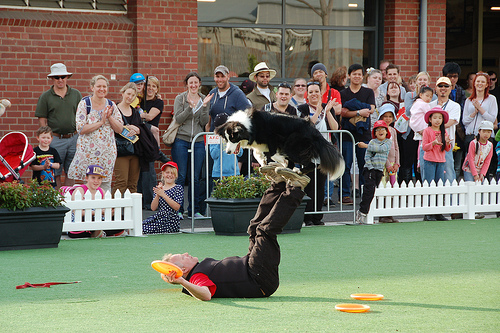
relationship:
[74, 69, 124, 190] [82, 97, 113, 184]
woman wearing dress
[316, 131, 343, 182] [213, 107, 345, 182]
tail of dog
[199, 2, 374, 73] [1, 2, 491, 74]
window on building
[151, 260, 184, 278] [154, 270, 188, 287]
frisbee in hand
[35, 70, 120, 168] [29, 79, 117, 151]
man wearing shirt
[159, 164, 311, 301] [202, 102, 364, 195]
entertainer performing stunt with dog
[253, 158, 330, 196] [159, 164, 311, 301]
shoes on entertainer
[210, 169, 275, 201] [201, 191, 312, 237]
plant on pot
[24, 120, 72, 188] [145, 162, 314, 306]
boy watching an entertainer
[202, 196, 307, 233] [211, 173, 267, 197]
pot with plant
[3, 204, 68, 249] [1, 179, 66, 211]
pot with plant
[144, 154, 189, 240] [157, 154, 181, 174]
girl wearing hat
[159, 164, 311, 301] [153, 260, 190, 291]
entertainer has hand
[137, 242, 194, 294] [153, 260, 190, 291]
frisbee in hand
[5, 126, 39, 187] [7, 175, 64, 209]
stroller by plants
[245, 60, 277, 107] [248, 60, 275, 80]
guy wearing hat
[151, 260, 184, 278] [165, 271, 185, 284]
frisbee in hand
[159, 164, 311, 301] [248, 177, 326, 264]
entertainer wearing pants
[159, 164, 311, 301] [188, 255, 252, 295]
entertainer wearing vest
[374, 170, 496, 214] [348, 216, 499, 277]
fence on lawn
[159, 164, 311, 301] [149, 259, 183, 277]
entertainer playing with frisbee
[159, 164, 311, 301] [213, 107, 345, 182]
entertainer playing with dog